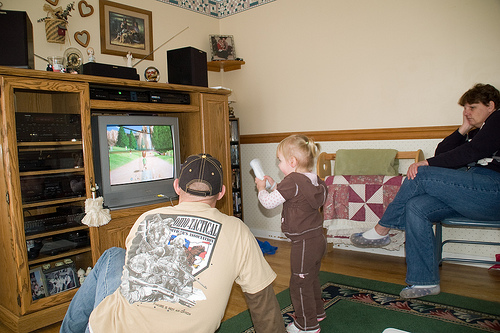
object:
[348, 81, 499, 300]
woman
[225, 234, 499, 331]
floor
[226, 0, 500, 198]
wall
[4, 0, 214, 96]
stereo system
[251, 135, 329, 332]
girl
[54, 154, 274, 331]
man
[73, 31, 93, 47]
hearts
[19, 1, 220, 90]
wall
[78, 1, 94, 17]
heats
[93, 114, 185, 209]
television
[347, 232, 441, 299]
slippers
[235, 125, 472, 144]
border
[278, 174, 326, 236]
shirt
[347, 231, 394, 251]
slipper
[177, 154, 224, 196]
hat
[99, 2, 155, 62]
picture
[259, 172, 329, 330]
clothes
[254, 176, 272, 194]
hand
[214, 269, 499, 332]
rug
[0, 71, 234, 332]
stand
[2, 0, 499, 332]
living room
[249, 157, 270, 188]
controller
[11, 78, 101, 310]
shelf